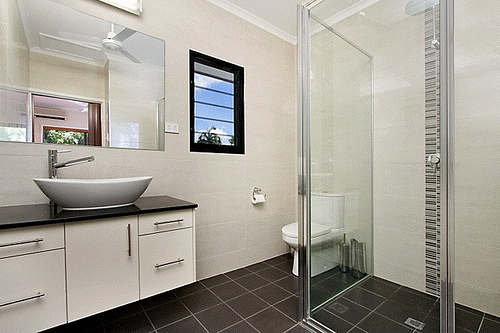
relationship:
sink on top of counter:
[30, 175, 153, 211] [1, 193, 197, 229]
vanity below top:
[0, 194, 198, 331] [0, 193, 197, 230]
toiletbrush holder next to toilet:
[339, 230, 349, 274] [275, 185, 350, 277]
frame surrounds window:
[187, 48, 245, 154] [194, 60, 236, 146]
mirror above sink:
[0, 0, 168, 151] [54, 148, 225, 267]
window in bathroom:
[188, 47, 246, 156] [1, 2, 498, 327]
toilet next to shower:
[281, 191, 345, 276] [294, 4, 499, 331]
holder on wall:
[253, 188, 265, 199] [234, 16, 301, 276]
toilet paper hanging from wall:
[252, 194, 266, 204] [246, 34, 291, 179]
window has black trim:
[194, 60, 236, 146] [188, 46, 245, 156]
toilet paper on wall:
[249, 186, 269, 206] [162, 4, 296, 270]